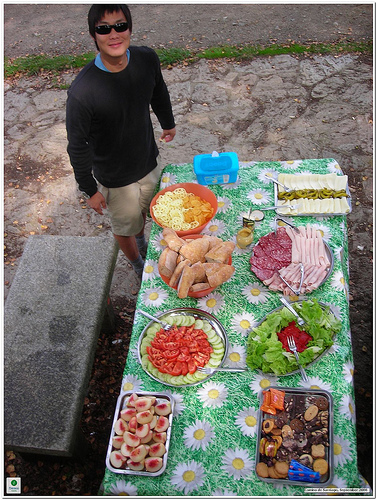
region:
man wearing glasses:
[82, 12, 141, 38]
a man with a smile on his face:
[83, 14, 168, 61]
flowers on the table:
[187, 409, 245, 471]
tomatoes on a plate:
[158, 335, 181, 366]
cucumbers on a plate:
[153, 373, 192, 393]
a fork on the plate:
[195, 356, 239, 384]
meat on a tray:
[259, 232, 287, 286]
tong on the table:
[280, 264, 310, 296]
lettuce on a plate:
[246, 333, 281, 378]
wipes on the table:
[207, 154, 242, 187]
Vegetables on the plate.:
[138, 308, 228, 385]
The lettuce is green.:
[244, 303, 340, 375]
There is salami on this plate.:
[253, 229, 290, 282]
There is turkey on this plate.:
[293, 228, 320, 285]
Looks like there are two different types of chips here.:
[153, 186, 217, 233]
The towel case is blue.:
[191, 151, 242, 182]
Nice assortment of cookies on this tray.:
[257, 385, 337, 489]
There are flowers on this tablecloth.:
[184, 392, 250, 492]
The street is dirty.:
[18, 153, 70, 215]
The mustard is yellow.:
[235, 228, 252, 245]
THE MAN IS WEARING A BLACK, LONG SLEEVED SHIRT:
[52, 30, 188, 200]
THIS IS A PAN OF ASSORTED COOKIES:
[245, 382, 342, 488]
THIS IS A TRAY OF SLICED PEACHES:
[98, 389, 178, 482]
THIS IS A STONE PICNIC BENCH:
[0, 223, 124, 464]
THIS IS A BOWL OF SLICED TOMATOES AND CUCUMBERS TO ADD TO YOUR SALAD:
[123, 305, 231, 386]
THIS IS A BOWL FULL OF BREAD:
[146, 217, 240, 320]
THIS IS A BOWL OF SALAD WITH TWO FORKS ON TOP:
[228, 294, 350, 381]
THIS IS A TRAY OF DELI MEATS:
[244, 218, 337, 292]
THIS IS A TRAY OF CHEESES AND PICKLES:
[268, 169, 366, 215]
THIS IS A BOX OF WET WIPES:
[189, 140, 246, 188]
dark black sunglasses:
[91, 21, 130, 34]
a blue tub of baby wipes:
[193, 151, 244, 184]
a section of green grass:
[7, 54, 91, 73]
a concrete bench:
[3, 233, 115, 459]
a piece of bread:
[172, 264, 196, 299]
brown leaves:
[5, 449, 22, 476]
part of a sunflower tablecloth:
[106, 390, 251, 496]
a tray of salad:
[247, 300, 334, 379]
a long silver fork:
[285, 335, 313, 381]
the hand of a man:
[87, 190, 110, 216]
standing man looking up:
[64, 5, 175, 278]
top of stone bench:
[0, 232, 116, 452]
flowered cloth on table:
[106, 156, 357, 491]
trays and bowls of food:
[105, 170, 351, 487]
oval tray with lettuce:
[250, 300, 334, 375]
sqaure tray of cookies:
[256, 386, 331, 484]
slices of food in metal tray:
[138, 307, 227, 385]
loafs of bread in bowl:
[160, 231, 234, 296]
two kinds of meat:
[254, 226, 326, 294]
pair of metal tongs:
[280, 267, 304, 295]